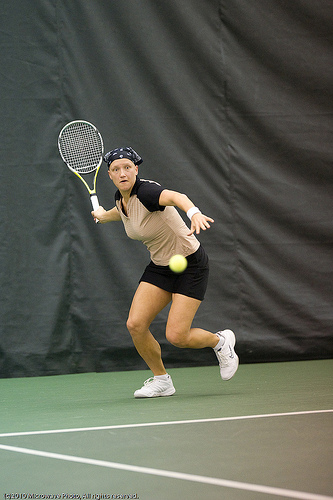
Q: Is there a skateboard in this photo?
A: No, there are no skateboards.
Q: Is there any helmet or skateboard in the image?
A: No, there are no skateboards or helmets.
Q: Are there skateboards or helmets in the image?
A: No, there are no skateboards or helmets.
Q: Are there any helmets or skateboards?
A: No, there are no skateboards or helmets.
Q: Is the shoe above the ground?
A: Yes, the shoe is above the ground.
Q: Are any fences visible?
A: No, there are no fences.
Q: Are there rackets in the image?
A: Yes, there is a racket.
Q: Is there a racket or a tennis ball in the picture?
A: Yes, there is a racket.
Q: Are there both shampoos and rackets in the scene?
A: No, there is a racket but no shampoos.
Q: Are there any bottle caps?
A: No, there are no bottle caps.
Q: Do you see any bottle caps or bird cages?
A: No, there are no bottle caps or bird cages.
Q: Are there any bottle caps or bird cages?
A: No, there are no bottle caps or bird cages.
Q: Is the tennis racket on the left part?
A: Yes, the tennis racket is on the left of the image.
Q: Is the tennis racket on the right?
A: No, the tennis racket is on the left of the image.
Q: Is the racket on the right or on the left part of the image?
A: The racket is on the left of the image.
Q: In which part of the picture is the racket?
A: The racket is on the left of the image.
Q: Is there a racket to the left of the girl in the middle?
A: Yes, there is a racket to the left of the girl.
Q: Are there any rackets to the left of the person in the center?
A: Yes, there is a racket to the left of the girl.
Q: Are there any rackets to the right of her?
A: No, the racket is to the left of the girl.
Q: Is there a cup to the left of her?
A: No, there is a racket to the left of the girl.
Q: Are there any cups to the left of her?
A: No, there is a racket to the left of the girl.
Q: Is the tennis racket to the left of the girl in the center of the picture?
A: Yes, the tennis racket is to the left of the girl.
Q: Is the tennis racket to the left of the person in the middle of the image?
A: Yes, the tennis racket is to the left of the girl.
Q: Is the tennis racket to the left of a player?
A: No, the tennis racket is to the left of the girl.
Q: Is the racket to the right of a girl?
A: No, the racket is to the left of a girl.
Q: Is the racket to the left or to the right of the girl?
A: The racket is to the left of the girl.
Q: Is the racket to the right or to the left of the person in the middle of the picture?
A: The racket is to the left of the girl.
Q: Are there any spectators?
A: No, there are no spectators.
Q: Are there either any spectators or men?
A: No, there are no spectators or men.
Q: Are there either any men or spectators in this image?
A: No, there are no spectators or men.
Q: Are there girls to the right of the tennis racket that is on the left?
A: Yes, there is a girl to the right of the racket.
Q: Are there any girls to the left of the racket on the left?
A: No, the girl is to the right of the racket.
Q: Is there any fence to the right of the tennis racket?
A: No, there is a girl to the right of the tennis racket.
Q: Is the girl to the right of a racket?
A: Yes, the girl is to the right of a racket.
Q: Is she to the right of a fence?
A: No, the girl is to the right of a racket.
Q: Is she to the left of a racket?
A: No, the girl is to the right of a racket.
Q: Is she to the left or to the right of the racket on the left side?
A: The girl is to the right of the racket.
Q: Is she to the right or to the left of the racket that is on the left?
A: The girl is to the right of the racket.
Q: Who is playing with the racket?
A: The girl is playing with the racket.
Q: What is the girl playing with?
A: The girl is playing with a racket.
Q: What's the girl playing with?
A: The girl is playing with a racket.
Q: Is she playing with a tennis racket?
A: Yes, the girl is playing with a tennis racket.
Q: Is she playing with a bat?
A: No, the girl is playing with a tennis racket.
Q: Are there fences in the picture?
A: No, there are no fences.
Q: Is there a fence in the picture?
A: No, there are no fences.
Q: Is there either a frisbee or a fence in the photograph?
A: No, there are no fences or frisbees.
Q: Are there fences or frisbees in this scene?
A: No, there are no fences or frisbees.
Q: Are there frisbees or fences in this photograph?
A: No, there are no fences or frisbees.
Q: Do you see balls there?
A: Yes, there is a ball.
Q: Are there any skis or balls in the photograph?
A: Yes, there is a ball.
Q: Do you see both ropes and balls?
A: No, there is a ball but no ropes.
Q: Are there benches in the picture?
A: No, there are no benches.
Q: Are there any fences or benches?
A: No, there are no benches or fences.